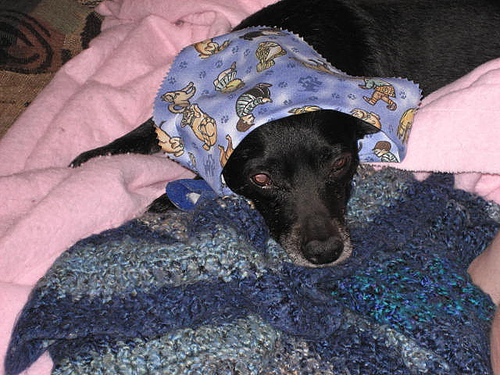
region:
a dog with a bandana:
[158, 31, 465, 302]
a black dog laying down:
[191, 66, 474, 315]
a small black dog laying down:
[133, 34, 448, 319]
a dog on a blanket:
[154, 48, 378, 254]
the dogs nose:
[297, 233, 344, 258]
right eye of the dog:
[242, 172, 277, 198]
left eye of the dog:
[330, 154, 348, 173]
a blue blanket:
[131, 267, 254, 353]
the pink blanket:
[76, 179, 122, 226]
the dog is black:
[346, 24, 436, 56]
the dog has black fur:
[333, 2, 435, 61]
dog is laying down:
[223, 18, 402, 281]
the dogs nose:
[310, 231, 339, 261]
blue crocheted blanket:
[21, 169, 498, 374]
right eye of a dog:
[250, 166, 278, 192]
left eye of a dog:
[323, 148, 350, 178]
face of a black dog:
[221, 110, 358, 267]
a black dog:
[58, 0, 499, 275]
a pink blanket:
[5, 3, 499, 373]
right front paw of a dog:
[60, 121, 158, 176]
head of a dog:
[211, 88, 367, 280]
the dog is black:
[200, 52, 372, 284]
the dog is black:
[231, 115, 366, 285]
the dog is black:
[227, 118, 374, 300]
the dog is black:
[232, 119, 382, 299]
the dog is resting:
[194, 74, 366, 284]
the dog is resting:
[208, 90, 350, 279]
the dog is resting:
[235, 117, 364, 286]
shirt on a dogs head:
[169, 43, 406, 161]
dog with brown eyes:
[252, 164, 272, 193]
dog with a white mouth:
[281, 224, 368, 284]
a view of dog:
[147, 64, 407, 296]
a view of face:
[219, 108, 376, 263]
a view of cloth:
[192, 63, 300, 145]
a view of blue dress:
[95, 233, 240, 328]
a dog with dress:
[183, 90, 381, 283]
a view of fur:
[274, 148, 319, 180]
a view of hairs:
[340, 25, 402, 74]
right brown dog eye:
[250, 166, 280, 191]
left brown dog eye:
[328, 149, 350, 181]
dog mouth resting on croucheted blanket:
[5, 162, 499, 372]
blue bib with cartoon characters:
[155, 21, 424, 196]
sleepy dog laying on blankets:
[68, 2, 498, 269]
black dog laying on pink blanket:
[68, 0, 497, 269]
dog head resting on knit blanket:
[222, 105, 384, 269]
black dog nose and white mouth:
[276, 213, 354, 269]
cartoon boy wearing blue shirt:
[233, 76, 271, 134]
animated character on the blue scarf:
[150, 121, 180, 151]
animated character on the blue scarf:
[162, 80, 194, 118]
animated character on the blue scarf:
[180, 100, 215, 150]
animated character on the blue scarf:
[235, 81, 271, 131]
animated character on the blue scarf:
[211, 60, 241, 100]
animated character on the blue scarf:
[251, 35, 277, 72]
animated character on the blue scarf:
[362, 77, 394, 113]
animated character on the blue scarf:
[350, 102, 381, 130]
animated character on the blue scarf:
[367, 140, 397, 162]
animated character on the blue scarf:
[229, 28, 284, 44]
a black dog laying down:
[90, 2, 498, 262]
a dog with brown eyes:
[230, 135, 362, 204]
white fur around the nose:
[285, 223, 359, 267]